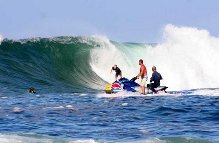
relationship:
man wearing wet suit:
[109, 64, 122, 80] [112, 66, 121, 78]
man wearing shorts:
[136, 54, 148, 95] [140, 78, 149, 87]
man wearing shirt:
[146, 66, 162, 93] [150, 73, 160, 83]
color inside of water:
[103, 42, 149, 55] [77, 102, 142, 119]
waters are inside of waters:
[72, 105, 117, 134] [0, 24, 219, 143]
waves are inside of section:
[163, 23, 209, 84] [168, 25, 214, 84]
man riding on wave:
[109, 64, 123, 80] [95, 56, 109, 81]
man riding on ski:
[146, 66, 162, 93] [128, 84, 167, 94]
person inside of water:
[22, 82, 39, 96] [11, 87, 28, 101]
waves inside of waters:
[0, 25, 219, 90] [0, 24, 219, 143]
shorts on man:
[134, 71, 162, 92] [124, 54, 145, 93]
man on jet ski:
[141, 63, 168, 86] [139, 81, 179, 97]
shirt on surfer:
[110, 64, 131, 77] [100, 65, 131, 85]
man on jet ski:
[135, 59, 148, 95] [111, 72, 151, 90]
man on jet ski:
[135, 59, 148, 95] [108, 74, 162, 99]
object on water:
[20, 81, 58, 101] [0, 25, 97, 137]